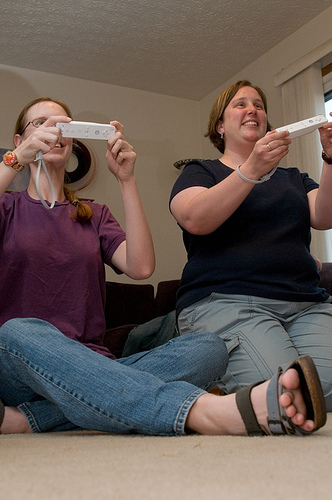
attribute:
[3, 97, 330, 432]
woman — sitting, seated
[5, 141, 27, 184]
watch — orange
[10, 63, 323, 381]
women — sitting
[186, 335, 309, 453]
sandals — leather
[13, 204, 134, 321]
shirt — purple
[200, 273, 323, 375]
pants — grey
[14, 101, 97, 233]
hair — braided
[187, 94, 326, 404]
woman — kneeling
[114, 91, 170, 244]
wall — white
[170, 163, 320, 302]
shirt — black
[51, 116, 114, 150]
controller — white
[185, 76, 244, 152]
hair — short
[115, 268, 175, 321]
sofa — brown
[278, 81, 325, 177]
blinds — white